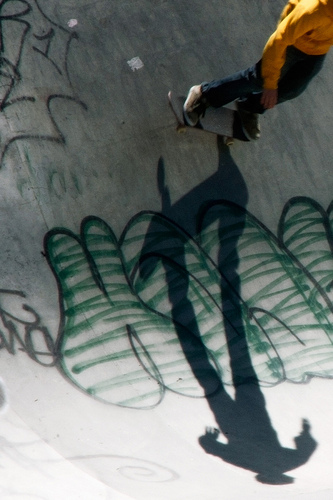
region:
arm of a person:
[261, 11, 303, 67]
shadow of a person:
[210, 419, 312, 482]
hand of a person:
[255, 80, 283, 112]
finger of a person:
[254, 87, 277, 109]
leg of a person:
[202, 56, 273, 117]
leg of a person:
[251, 66, 311, 118]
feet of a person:
[238, 102, 262, 138]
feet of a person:
[178, 75, 218, 122]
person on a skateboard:
[152, 87, 275, 146]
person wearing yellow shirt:
[273, 1, 331, 63]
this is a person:
[176, 0, 332, 157]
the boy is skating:
[189, 3, 326, 112]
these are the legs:
[210, 78, 261, 123]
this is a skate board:
[164, 90, 185, 119]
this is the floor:
[22, 80, 167, 196]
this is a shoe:
[183, 83, 208, 121]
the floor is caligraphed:
[61, 245, 222, 382]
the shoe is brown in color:
[186, 83, 204, 117]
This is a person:
[191, 9, 331, 207]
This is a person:
[177, 2, 328, 171]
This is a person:
[184, 3, 328, 160]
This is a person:
[177, 0, 331, 165]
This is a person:
[170, 1, 331, 165]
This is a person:
[185, 1, 331, 192]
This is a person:
[157, 1, 331, 169]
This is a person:
[167, 2, 331, 147]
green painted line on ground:
[51, 231, 109, 248]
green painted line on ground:
[56, 238, 104, 257]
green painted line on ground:
[59, 248, 118, 262]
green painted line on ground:
[70, 280, 127, 298]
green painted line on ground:
[67, 286, 128, 315]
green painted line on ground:
[65, 305, 136, 334]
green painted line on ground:
[101, 313, 156, 322]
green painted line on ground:
[63, 317, 165, 355]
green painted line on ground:
[85, 352, 202, 397]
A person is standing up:
[191, 2, 316, 138]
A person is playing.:
[194, 9, 315, 162]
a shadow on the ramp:
[133, 125, 315, 487]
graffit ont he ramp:
[52, 173, 193, 438]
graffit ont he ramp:
[122, 227, 216, 391]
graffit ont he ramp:
[209, 212, 299, 381]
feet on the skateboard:
[173, 94, 273, 214]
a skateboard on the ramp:
[141, 72, 269, 151]